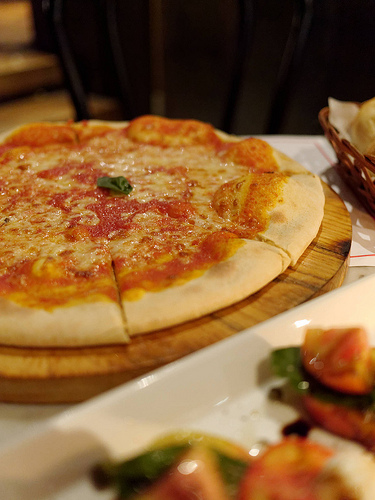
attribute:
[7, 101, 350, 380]
pizza — cheese, part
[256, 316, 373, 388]
food — shiny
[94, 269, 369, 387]
platter — white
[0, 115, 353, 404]
tray — wooden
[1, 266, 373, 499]
plate — square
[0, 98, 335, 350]
pizza — cheese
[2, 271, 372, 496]
tray — white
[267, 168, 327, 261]
crust — lightly baked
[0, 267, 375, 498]
serving tray — white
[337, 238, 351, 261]
circle — black 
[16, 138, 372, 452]
food — varied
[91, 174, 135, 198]
sprig — small, green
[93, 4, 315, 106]
backrest — black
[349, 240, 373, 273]
napkin — white, red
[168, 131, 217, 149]
cheese pizza — part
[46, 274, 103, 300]
cheese pizza — part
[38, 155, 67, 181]
cheese pizza — part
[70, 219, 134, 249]
cheese pizza — part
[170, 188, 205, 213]
cheese pizza — part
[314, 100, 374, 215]
basket — wicker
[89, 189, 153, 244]
sauce — red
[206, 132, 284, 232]
air pockets — large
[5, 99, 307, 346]
pizza — cheese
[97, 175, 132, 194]
vegetable — green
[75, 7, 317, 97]
rungs — black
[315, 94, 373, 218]
basket — small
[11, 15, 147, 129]
stairs — wooden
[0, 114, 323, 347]
pizza — on, sliced, cheese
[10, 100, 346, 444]
board — cutting, wooden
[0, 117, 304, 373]
pizza toppings — tomato